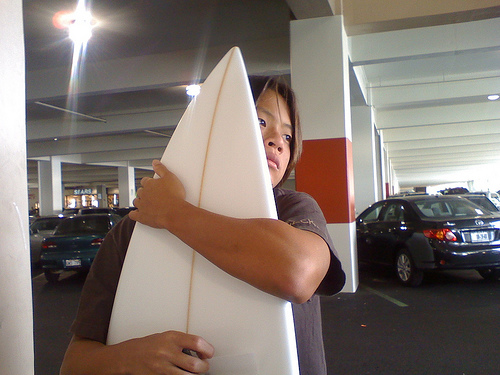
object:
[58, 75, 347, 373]
person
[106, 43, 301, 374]
surfboard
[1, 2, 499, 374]
building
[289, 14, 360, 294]
pillar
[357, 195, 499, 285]
car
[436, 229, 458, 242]
light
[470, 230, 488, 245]
number plate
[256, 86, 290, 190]
face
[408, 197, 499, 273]
back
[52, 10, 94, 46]
light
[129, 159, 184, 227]
hand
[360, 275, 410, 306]
line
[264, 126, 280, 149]
nose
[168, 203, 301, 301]
forearm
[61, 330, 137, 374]
forearm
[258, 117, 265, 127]
eye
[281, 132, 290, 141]
right eye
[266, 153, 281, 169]
mouth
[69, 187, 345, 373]
shirt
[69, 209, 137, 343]
sleeve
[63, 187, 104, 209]
store